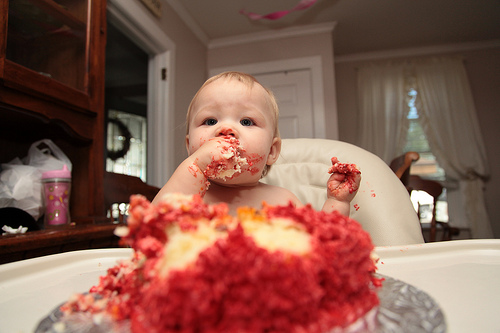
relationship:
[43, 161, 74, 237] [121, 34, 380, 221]
bottle of baby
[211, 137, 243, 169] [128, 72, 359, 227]
mouth on baby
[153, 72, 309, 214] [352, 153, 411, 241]
baby in high chair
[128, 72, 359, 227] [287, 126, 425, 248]
baby sitting in high chair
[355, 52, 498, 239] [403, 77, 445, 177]
white curtain in window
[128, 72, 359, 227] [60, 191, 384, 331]
baby eating cake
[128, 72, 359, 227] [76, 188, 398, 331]
baby eats cake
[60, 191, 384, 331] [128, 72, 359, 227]
cake in front baby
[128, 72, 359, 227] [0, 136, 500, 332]
baby eating in chair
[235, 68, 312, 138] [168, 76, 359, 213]
door behind baby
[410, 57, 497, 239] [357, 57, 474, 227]
white curtain on window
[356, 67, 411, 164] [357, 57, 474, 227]
curtain on window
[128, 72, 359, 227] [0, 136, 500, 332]
baby in chair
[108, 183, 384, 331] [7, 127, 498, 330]
cake on chair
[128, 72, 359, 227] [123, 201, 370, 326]
baby enjoying cake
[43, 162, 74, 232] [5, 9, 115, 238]
bottle on china cabinet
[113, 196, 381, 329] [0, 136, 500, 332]
frosting on chair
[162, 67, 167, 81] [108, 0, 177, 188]
hinge on door frame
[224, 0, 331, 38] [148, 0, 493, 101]
streamer on ceiling